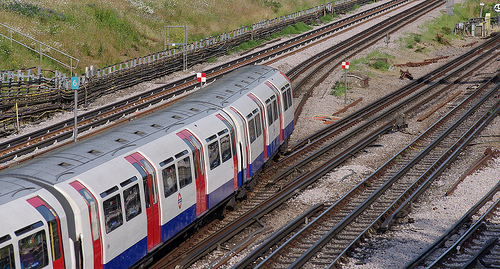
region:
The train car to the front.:
[190, 60, 325, 178]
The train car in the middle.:
[31, 99, 265, 262]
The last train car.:
[3, 168, 90, 263]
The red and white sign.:
[338, 55, 360, 102]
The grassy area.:
[1, 1, 324, 88]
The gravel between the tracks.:
[343, 153, 493, 268]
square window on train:
[148, 163, 185, 198]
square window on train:
[20, 216, 57, 266]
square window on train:
[91, 182, 123, 233]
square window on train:
[124, 175, 148, 225]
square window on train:
[172, 149, 193, 189]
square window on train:
[210, 129, 228, 184]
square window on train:
[218, 121, 235, 163]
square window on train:
[238, 105, 260, 150]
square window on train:
[254, 99, 271, 141]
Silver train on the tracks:
[1, 63, 298, 267]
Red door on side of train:
[123, 149, 163, 254]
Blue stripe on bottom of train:
[98, 233, 155, 268]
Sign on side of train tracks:
[69, 74, 80, 142]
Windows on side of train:
[99, 174, 147, 234]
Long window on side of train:
[69, 177, 105, 267]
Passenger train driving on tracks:
[3, 62, 306, 267]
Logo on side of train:
[175, 193, 183, 207]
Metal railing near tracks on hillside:
[1, 20, 79, 78]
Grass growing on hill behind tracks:
[2, 0, 344, 70]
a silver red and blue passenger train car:
[185, 63, 294, 186]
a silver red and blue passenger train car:
[1, 174, 68, 267]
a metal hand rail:
[1, 21, 78, 74]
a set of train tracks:
[0, 0, 405, 162]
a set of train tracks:
[282, 0, 445, 120]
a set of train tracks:
[402, 182, 498, 267]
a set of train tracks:
[235, 74, 498, 265]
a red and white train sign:
[340, 59, 350, 69]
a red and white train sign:
[194, 71, 206, 83]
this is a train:
[10, 2, 330, 266]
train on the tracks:
[3, 19, 413, 267]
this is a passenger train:
[6, 43, 298, 265]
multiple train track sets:
[259, 85, 497, 265]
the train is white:
[0, 54, 337, 259]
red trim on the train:
[109, 136, 191, 248]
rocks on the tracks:
[374, 153, 493, 256]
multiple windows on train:
[25, 5, 328, 243]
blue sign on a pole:
[45, 48, 92, 142]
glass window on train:
[2, 245, 13, 265]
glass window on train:
[17, 230, 47, 266]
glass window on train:
[102, 192, 123, 232]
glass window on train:
[122, 182, 138, 218]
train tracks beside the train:
[316, 177, 381, 266]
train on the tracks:
[0, 133, 252, 231]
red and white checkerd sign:
[340, 58, 350, 70]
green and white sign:
[70, 71, 82, 94]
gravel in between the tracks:
[437, 200, 456, 219]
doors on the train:
[133, 152, 164, 248]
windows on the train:
[100, 192, 143, 217]